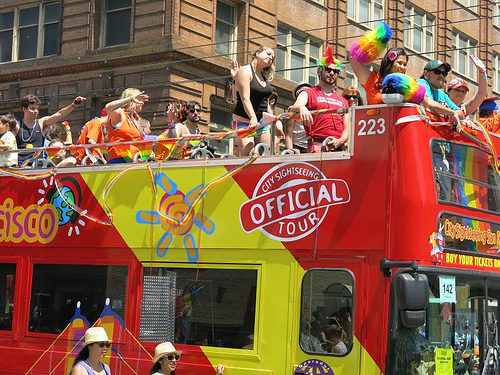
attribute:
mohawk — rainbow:
[320, 46, 337, 69]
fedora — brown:
[78, 321, 110, 347]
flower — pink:
[388, 47, 401, 62]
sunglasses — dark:
[188, 107, 201, 112]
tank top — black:
[236, 62, 271, 118]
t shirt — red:
[299, 82, 346, 132]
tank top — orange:
[110, 111, 144, 157]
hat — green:
[424, 56, 453, 76]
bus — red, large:
[0, 106, 495, 370]